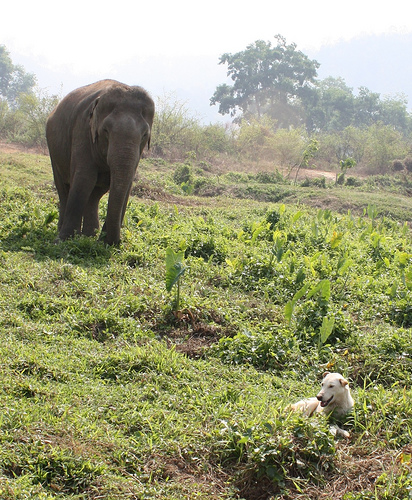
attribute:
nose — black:
[314, 392, 329, 404]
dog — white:
[285, 369, 359, 435]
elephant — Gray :
[40, 77, 156, 247]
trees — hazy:
[200, 36, 323, 133]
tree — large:
[202, 27, 323, 141]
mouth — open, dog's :
[291, 364, 362, 448]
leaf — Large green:
[159, 253, 183, 288]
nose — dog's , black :
[310, 391, 332, 408]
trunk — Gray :
[105, 128, 143, 249]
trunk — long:
[105, 136, 128, 226]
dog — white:
[282, 364, 370, 434]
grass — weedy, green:
[0, 150, 410, 497]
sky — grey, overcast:
[0, 0, 410, 74]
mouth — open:
[313, 387, 334, 409]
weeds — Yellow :
[65, 236, 112, 263]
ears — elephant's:
[86, 92, 101, 143]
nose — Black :
[317, 390, 330, 404]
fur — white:
[300, 397, 317, 412]